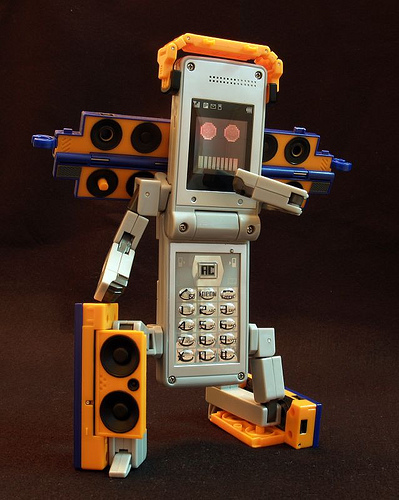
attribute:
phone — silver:
[154, 53, 270, 389]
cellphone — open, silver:
[143, 52, 340, 445]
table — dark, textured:
[8, 314, 396, 494]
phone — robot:
[82, 46, 316, 406]